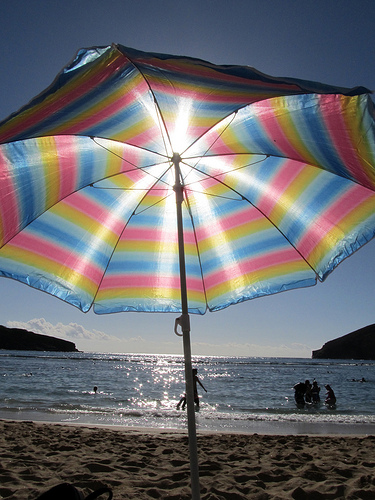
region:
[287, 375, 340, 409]
four people together in the water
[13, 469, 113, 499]
a bag in the sand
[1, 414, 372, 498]
trampled grey sand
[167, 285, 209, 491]
an umbrella pole in the sand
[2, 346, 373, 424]
shiny blue water in a bay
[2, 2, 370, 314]
a yellow, pink, blue, and white umbrella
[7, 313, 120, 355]
clouds peeking over a hill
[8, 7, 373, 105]
a dark blue sky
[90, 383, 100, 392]
a head in the water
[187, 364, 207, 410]
a man behind an umbrella pole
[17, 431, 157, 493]
The sand is brown.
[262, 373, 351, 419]
A group of people are in the water.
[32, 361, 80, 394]
The water is slightly choppy.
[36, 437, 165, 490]
The sand has a lot of tracks in it.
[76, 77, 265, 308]
The sun is shining through the umbrella.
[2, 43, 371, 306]
The umbrella is white, blue, yellow and red.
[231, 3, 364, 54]
The sky is blue.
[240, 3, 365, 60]
The sky is clear.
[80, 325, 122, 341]
A few clouds are in the sky.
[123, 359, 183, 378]
The sun is reflecting on the water.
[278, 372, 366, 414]
group of people in the water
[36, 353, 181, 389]
a body of water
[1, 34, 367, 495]
tall beach umbrella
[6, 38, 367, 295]
yellow blue red white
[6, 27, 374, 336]
yellow, blue, pink umbrella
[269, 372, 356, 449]
a group of people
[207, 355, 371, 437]
a body of water with people in it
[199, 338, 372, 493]
people at the beach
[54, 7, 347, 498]
beach umbrella in the sand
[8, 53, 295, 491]
umbrella in the sand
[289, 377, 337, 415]
four people playing in water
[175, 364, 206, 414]
man walking his dog in the surf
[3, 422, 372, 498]
many footprints in the sand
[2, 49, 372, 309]
rainbow stripes on beach umbrella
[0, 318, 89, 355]
black rocky cliff in background on left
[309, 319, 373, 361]
black rocky cliff in background on right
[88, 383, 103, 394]
person's head poking out of water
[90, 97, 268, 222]
eight segments of umbrella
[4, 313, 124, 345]
one lonely puffy cloud in sky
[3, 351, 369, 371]
line of rocks off the shore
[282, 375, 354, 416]
group of people in the water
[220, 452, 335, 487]
footprints in the sand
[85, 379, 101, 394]
lone boy bobbing in the water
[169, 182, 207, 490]
adjustable umbrella pole in the sand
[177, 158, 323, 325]
striped panel of an umbrella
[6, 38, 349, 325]
blue yellow and pink umbrella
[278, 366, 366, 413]
people swimming in the water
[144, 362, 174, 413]
sun glinting off the water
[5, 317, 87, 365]
rocky outcropping in the distance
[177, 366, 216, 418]
man playing with his son in the water